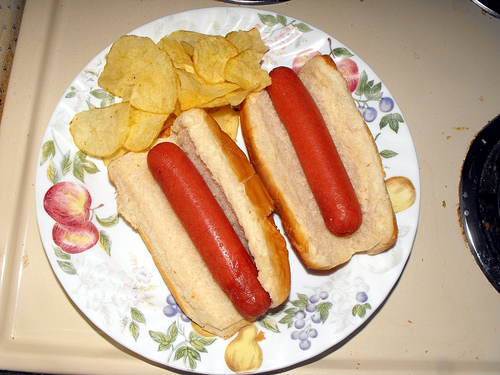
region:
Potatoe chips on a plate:
[78, 20, 278, 122]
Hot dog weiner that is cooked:
[142, 150, 266, 315]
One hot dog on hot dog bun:
[88, 125, 283, 325]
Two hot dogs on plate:
[112, 82, 444, 328]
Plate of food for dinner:
[25, 3, 433, 373]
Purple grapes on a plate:
[285, 320, 323, 357]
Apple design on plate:
[38, 173, 106, 259]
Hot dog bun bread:
[365, 200, 395, 247]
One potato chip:
[62, 103, 135, 150]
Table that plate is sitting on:
[406, 276, 468, 341]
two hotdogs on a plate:
[82, 27, 397, 348]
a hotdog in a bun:
[102, 112, 303, 336]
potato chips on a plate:
[74, 26, 266, 144]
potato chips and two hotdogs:
[72, 24, 381, 336]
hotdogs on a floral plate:
[47, 22, 407, 366]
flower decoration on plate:
[26, 147, 122, 285]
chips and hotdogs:
[80, 34, 402, 356]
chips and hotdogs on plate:
[82, 17, 378, 324]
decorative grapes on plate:
[272, 281, 354, 357]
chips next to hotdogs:
[87, 11, 278, 148]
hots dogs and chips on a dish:
[61, 14, 451, 357]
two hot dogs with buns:
[143, 112, 350, 310]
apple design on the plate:
[41, 172, 118, 286]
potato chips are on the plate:
[90, 24, 267, 116]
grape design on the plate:
[289, 289, 370, 354]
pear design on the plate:
[216, 323, 278, 369]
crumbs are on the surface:
[416, 65, 487, 290]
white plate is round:
[33, 5, 414, 356]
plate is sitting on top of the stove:
[391, 80, 486, 307]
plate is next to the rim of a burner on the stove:
[392, 75, 494, 304]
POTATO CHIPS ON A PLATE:
[67, 22, 282, 162]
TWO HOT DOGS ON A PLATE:
[105, 42, 405, 342]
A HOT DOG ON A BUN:
[117, 100, 297, 330]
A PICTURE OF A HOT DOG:
[147, 116, 282, 322]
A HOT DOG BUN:
[237, 40, 397, 275]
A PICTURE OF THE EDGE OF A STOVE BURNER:
[451, 110, 496, 305]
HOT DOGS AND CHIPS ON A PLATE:
[31, 1, 422, 374]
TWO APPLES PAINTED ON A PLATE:
[41, 178, 121, 274]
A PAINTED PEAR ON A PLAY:
[217, 318, 278, 373]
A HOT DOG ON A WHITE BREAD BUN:
[111, 99, 296, 339]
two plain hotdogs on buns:
[93, 51, 403, 341]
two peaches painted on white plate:
[39, 178, 109, 254]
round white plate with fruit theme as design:
[36, 5, 423, 368]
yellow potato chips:
[68, 26, 270, 154]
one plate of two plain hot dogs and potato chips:
[33, 8, 416, 366]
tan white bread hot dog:
[106, 160, 241, 340]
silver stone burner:
[451, 111, 498, 301]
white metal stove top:
[5, 4, 493, 374]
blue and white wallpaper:
[0, 0, 24, 103]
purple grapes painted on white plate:
[153, 294, 188, 334]